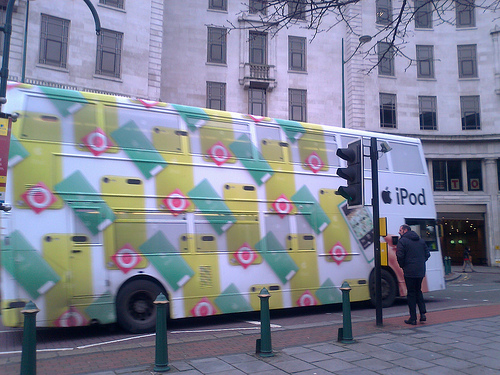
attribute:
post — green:
[339, 278, 354, 342]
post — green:
[253, 285, 273, 355]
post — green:
[152, 290, 169, 372]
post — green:
[16, 299, 39, 373]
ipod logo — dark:
[395, 184, 428, 208]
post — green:
[252, 286, 277, 358]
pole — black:
[368, 135, 383, 327]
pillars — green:
[78, 291, 439, 363]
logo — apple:
[382, 187, 392, 203]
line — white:
[246, 314, 281, 328]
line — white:
[170, 324, 264, 334]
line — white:
[75, 333, 159, 352]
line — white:
[5, 345, 72, 354]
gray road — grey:
[443, 270, 499, 304]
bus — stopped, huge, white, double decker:
[0, 76, 449, 333]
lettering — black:
[387, 186, 429, 209]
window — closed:
[36, 10, 71, 70]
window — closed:
[97, 27, 122, 78]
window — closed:
[100, 0, 123, 14]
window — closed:
[205, 26, 227, 65]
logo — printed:
[356, 176, 438, 206]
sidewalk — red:
[0, 302, 498, 374]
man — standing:
[396, 224, 431, 324]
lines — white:
[1, 319, 280, 357]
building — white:
[21, 14, 493, 363]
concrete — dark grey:
[412, 313, 494, 370]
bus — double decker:
[0, 81, 461, 364]